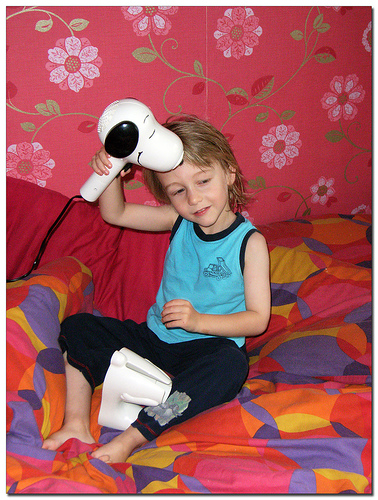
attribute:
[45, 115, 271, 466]
child — light skinned, barefoot, enjoying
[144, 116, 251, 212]
hair — wet, blonde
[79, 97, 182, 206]
blow dryer — white, snoopy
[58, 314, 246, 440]
pyjamas — black, blue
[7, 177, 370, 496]
bed — colorful, pink, multi colored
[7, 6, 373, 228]
wallpaper — floral, patterned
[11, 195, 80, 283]
wire — black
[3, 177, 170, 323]
pillow — red, pink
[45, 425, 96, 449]
foot — bare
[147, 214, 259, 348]
shirt — blue, sleeveless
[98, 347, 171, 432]
holder — plastic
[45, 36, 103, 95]
flower — white, pink